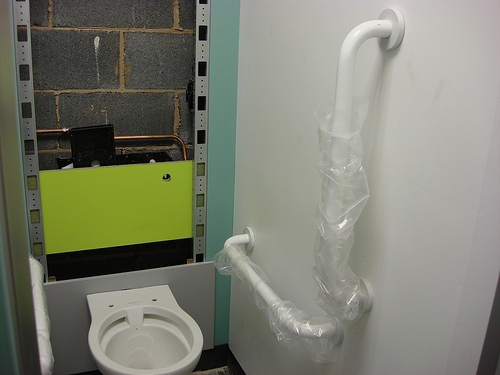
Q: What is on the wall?
A: Standing bar.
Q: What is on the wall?
A: Green board.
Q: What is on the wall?
A: Grey cement blocks.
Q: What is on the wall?
A: Metal beams.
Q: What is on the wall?
A: White toilet.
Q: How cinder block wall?
A: Gray.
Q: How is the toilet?
A: Lidless.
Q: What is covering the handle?
A: A plastic cover.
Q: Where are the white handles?
A: On the wall.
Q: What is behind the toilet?
A: Cinder blocks and copper pipes.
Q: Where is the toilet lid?
A: Not on the toilet.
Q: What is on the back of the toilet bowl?
A: Holes.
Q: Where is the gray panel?
A: On the back of the toilet.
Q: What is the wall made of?
A: Cinder blocks.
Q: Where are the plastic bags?
A: Over grab bars.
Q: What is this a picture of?
A: A restroom.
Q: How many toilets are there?
A: One.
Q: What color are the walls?
A: White.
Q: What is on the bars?
A: Plastic.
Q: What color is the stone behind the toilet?
A: Gray.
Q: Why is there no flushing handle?
A: The restroom is unfinished.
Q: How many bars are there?
A: Three.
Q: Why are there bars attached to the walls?
A: To help a handicapped person to use the toilet.